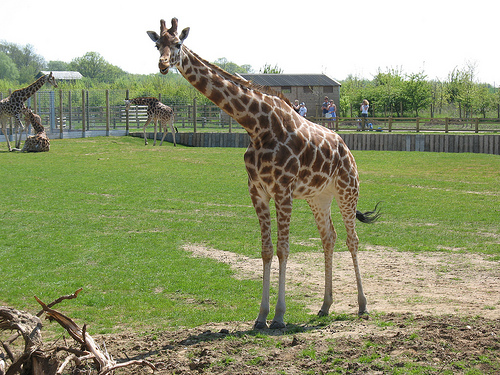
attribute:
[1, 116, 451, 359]
area — viewing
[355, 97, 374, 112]
shirt — white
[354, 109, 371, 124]
pants — blue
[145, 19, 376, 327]
giraffe — brown, white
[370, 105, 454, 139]
wooden braches — pile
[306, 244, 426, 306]
dry dead grass — patch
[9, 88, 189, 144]
wooden picket fence — enclosure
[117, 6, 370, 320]
giraffe — walking around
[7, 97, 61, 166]
giraffe laying — laying down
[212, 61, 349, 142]
exhibit building — gray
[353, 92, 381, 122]
woman — wearing white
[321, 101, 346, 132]
woman wearing blue — wearing blue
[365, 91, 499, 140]
exhibit fence — wooden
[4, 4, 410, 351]
giraffe exhibit — green, grassy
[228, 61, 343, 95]
building roof — distant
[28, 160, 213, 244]
grassy field — green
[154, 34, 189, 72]
face of a giraffe — white, brown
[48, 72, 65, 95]
face of a giraffe — brown, white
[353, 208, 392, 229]
tail of a giraffe — black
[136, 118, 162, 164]
leg of a giraffe — spotted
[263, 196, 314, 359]
leg of a giraffe — brown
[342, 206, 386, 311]
leg of a giraffe — brown spotted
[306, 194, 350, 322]
leg of a giraffe — spotted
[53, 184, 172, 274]
giraffe in a grassy — spotted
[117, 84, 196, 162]
giraffe — tall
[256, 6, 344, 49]
white clouds — puffy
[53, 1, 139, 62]
louds in blue sky — puffy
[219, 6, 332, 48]
white clouds in — white glare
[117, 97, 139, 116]
head of the giraffe — brown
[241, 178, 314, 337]
legs of the giraffe — skinny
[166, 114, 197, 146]
"tail of the giraffe — black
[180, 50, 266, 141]
neck of the giraffe — long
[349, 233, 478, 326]
grass on the ground — green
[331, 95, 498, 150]
fence in distance — metal, wooden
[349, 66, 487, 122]
trees in  distance — green